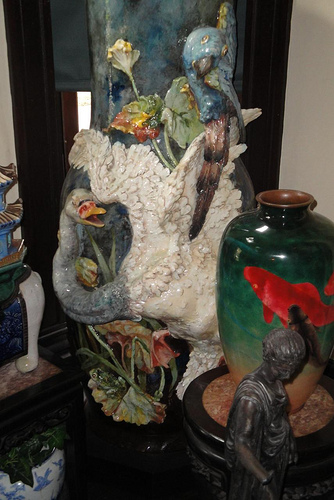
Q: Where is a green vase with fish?
A: On a table.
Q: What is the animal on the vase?
A: A fish.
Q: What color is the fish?
A: Red.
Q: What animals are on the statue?
A: Birds.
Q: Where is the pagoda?
A: Next to the bird statue.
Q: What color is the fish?
A: Red.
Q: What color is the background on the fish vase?
A: Green.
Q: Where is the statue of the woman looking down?
A: In front of the vase with the fish.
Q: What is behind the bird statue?
A: A window.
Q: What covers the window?
A: A blind.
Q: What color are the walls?
A: White.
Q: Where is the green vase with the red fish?
A: Behind the woman statue.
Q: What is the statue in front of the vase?
A: A statue of a woman.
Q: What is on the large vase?
A: A goose.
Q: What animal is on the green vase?
A: A fish.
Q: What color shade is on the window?
A: Blue.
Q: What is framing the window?
A: Wood.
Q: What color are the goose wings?
A: White.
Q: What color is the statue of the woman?
A: Black.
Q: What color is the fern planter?
A: Blue and white.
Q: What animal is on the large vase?
A: Swan.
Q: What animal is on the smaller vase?
A: Fish.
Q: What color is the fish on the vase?
A: Red.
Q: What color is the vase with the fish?
A: Green.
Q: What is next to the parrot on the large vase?
A: Green and red lillies.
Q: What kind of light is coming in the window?
A: Sunlight.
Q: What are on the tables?
A: Vases.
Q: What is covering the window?
A: A shade.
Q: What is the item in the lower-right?
A: A statue.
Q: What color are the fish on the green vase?
A: Red.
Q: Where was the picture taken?
A: In an art collector's home.